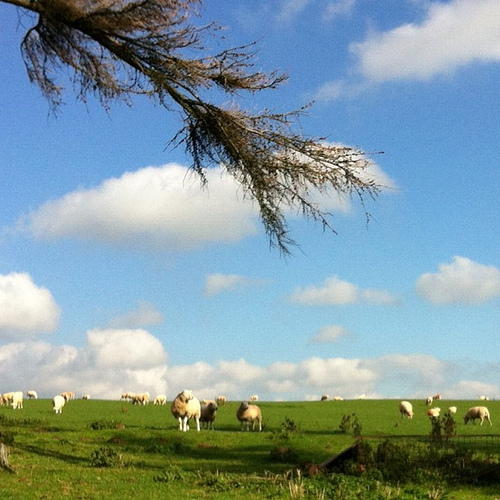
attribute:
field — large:
[2, 397, 499, 499]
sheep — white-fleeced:
[171, 390, 201, 432]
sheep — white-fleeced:
[399, 398, 414, 418]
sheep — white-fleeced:
[445, 402, 456, 419]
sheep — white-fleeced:
[461, 406, 491, 424]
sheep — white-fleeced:
[235, 402, 262, 430]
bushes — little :
[298, 401, 378, 461]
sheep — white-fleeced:
[203, 398, 223, 428]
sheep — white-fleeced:
[120, 386, 152, 410]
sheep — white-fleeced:
[235, 397, 272, 434]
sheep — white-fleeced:
[51, 393, 70, 420]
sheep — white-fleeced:
[463, 404, 498, 429]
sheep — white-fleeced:
[152, 393, 167, 404]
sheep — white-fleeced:
[393, 391, 418, 425]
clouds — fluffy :
[7, 122, 434, 266]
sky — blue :
[12, 162, 229, 297]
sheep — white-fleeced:
[227, 377, 269, 440]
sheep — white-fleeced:
[7, 386, 27, 415]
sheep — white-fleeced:
[382, 383, 416, 426]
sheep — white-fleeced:
[31, 383, 69, 418]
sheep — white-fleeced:
[462, 406, 492, 429]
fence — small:
[360, 426, 494, 489]